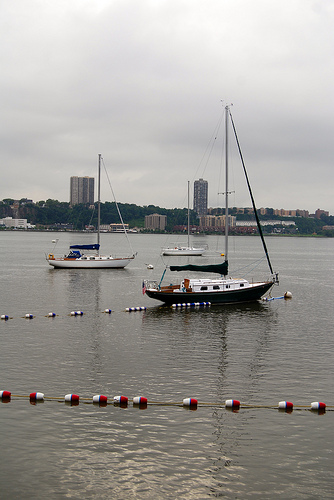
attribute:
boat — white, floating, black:
[146, 104, 277, 305]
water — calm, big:
[3, 230, 332, 498]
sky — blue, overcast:
[0, 1, 330, 214]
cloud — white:
[102, 17, 246, 97]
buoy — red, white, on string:
[182, 395, 196, 411]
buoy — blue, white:
[47, 311, 55, 319]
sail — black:
[170, 261, 232, 278]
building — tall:
[73, 179, 94, 210]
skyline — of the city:
[4, 176, 333, 234]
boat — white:
[52, 152, 135, 271]